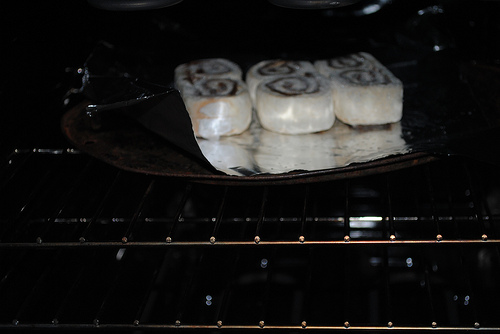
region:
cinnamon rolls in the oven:
[147, 43, 422, 138]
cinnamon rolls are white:
[105, 40, 412, 205]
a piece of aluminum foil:
[190, 122, 422, 180]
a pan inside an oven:
[37, 55, 484, 187]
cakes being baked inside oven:
[162, 42, 416, 139]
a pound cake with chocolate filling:
[179, 74, 260, 140]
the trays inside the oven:
[6, 209, 498, 259]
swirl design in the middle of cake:
[254, 69, 338, 132]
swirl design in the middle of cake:
[327, 67, 409, 124]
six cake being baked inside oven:
[170, 42, 403, 146]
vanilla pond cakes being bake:
[162, 44, 420, 136]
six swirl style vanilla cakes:
[157, 39, 420, 141]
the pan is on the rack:
[47, 29, 469, 190]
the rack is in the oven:
[2, 75, 487, 299]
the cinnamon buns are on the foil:
[145, 19, 412, 154]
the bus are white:
[126, 35, 410, 162]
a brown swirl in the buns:
[163, 44, 327, 132]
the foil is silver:
[140, 100, 420, 178]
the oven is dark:
[67, 17, 473, 310]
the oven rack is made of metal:
[92, 195, 456, 267]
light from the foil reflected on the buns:
[230, 99, 342, 147]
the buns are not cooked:
[154, 32, 413, 188]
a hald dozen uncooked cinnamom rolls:
[163, 46, 405, 128]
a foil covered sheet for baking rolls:
[53, 71, 421, 162]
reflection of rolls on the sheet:
[147, 115, 430, 177]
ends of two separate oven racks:
[10, 228, 498, 331]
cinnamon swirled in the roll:
[190, 71, 237, 103]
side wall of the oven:
[0, 4, 41, 333]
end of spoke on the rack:
[116, 230, 130, 247]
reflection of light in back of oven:
[343, 206, 405, 233]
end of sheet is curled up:
[45, 83, 188, 190]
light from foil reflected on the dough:
[198, 99, 311, 133]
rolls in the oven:
[171, 47, 406, 134]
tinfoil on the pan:
[208, 140, 341, 155]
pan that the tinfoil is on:
[116, 145, 176, 173]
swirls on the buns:
[197, 73, 232, 95]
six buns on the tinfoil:
[177, 55, 407, 131]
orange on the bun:
[192, 99, 219, 131]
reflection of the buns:
[262, 144, 350, 156]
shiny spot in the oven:
[348, 207, 388, 232]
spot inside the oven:
[198, 278, 218, 310]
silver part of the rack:
[82, 235, 168, 248]